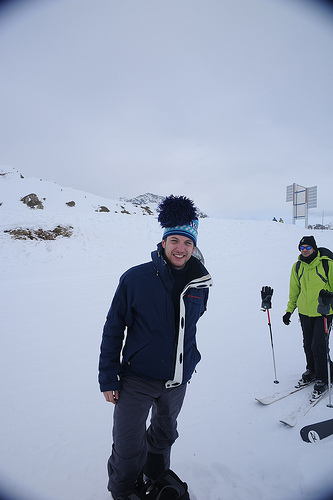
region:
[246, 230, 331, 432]
skier in green jacket on the side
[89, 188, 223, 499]
skier in the snow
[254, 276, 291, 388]
glove on top of ski pole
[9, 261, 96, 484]
white snow on the ground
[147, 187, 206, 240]
blue pompom hat of skier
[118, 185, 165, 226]
snowy mountain in the background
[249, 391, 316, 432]
white skis on the skier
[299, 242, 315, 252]
sunglasses on face of skier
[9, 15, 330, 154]
grey cloudy sky in the distance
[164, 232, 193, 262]
face of the skier posing for camera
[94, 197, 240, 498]
man smiling, standing in the snow wearing warm clothes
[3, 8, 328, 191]
gray skies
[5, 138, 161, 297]
hills in the snow with some rocks and bushes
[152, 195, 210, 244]
winter hat with fluffy topper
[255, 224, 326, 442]
man in green yellow jacket on skis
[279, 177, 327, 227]
back of signs in the snow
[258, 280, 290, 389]
glove on a ski pole in the snow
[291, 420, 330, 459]
end of one ski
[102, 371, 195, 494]
snow pants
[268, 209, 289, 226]
trees poking out behind snowy hill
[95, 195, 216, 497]
a person wearing a jacket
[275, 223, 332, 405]
a person wearing a jacket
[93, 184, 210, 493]
a person wearing a hat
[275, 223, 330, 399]
a person wearing a hat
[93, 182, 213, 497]
a person wearing trousers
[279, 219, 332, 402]
a person wearing trousers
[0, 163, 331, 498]
white cold ice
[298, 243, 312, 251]
a pair of blue glasses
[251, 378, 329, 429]
white skis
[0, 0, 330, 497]
it is a daytime scene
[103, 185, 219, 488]
man on skiis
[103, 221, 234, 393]
man in navy blue ski jacket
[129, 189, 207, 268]
man with blue cap and black fuzz ball on top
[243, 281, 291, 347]
glove resting on ski pole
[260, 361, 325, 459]
three skiis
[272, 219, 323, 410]
man on skis with green jacket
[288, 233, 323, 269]
man with blue sunglasses on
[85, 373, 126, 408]
man is not wearing a glove on this hand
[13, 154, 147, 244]
background of the ski slopes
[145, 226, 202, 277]
man smiling at camera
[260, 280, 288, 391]
The man's ski pole for his right hand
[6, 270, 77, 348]
A small patch of snow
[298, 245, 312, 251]
Male's light blue sunglasses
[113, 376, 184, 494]
The young man's gray sweatpants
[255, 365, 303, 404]
The elder man's right ski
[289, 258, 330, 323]
Elder man's green sweater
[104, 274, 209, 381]
Young man's blue's sweater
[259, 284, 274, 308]
Elder man's black glove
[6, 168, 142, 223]
A small snowy hill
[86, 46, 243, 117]
Clear overcast sky